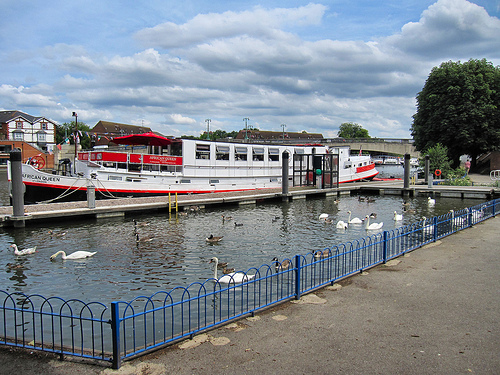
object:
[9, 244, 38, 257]
goose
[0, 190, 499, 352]
water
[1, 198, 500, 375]
fence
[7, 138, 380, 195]
boat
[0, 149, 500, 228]
pier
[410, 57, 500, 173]
tree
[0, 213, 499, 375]
concrete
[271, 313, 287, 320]
stain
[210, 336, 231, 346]
stain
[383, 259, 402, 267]
stain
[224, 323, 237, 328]
stain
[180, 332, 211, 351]
stain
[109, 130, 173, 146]
canopy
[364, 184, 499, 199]
dock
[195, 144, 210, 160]
window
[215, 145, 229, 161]
window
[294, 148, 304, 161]
window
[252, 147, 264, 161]
window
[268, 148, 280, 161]
window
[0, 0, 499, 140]
sky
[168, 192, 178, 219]
ladder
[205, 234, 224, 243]
duck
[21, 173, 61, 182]
words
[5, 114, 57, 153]
house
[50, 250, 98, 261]
swan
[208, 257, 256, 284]
swan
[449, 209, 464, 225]
swan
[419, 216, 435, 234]
swan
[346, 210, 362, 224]
swan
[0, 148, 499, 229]
bridge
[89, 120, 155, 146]
building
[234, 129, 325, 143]
building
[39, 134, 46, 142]
window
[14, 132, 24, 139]
window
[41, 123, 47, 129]
window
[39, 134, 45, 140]
window